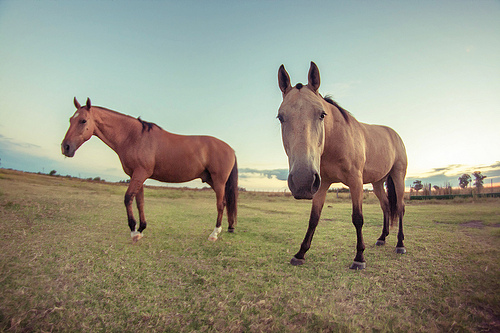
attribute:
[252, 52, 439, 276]
horse — black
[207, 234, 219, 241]
hoof — white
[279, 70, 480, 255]
horse — light brown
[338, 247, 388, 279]
hoof — small, grey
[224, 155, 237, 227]
tail — brown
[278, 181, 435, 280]
legs — dark brown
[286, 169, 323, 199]
nose — brown, large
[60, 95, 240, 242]
horse — brown, chocolate brown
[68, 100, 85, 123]
blaze — white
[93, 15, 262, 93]
sky — open, blue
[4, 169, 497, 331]
trim grass — green, trimmed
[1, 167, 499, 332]
grass — green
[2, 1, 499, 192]
sky — light blue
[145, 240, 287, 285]
grass — short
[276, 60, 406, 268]
horses — standing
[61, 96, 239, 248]
horses — standing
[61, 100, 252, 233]
horse — brown, dark colored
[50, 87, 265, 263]
horse — brown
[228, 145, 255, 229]
tail — long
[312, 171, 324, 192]
horse nostril — large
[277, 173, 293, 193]
horse nostril — large